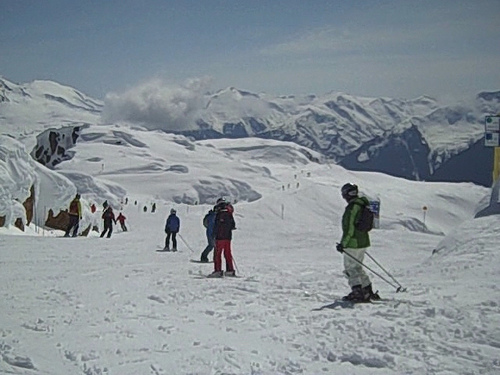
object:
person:
[335, 183, 381, 302]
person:
[164, 208, 181, 251]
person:
[100, 207, 117, 239]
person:
[205, 202, 237, 277]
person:
[200, 198, 227, 262]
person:
[63, 194, 83, 238]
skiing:
[0, 166, 408, 318]